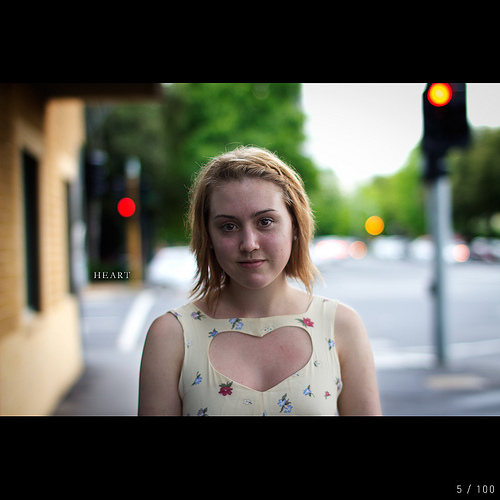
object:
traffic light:
[117, 197, 137, 219]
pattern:
[206, 323, 313, 395]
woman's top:
[162, 292, 347, 417]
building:
[0, 74, 83, 416]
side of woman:
[134, 307, 189, 415]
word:
[94, 271, 102, 280]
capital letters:
[93, 271, 131, 280]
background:
[77, 82, 499, 414]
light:
[427, 82, 454, 108]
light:
[364, 215, 385, 237]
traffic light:
[423, 81, 458, 108]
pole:
[427, 175, 452, 373]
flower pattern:
[277, 393, 294, 415]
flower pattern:
[191, 370, 203, 387]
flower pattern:
[228, 318, 244, 331]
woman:
[134, 142, 381, 417]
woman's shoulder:
[140, 305, 198, 357]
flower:
[217, 380, 233, 397]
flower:
[293, 316, 315, 329]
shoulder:
[301, 296, 371, 353]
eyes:
[219, 223, 239, 233]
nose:
[239, 226, 260, 253]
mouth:
[233, 258, 268, 270]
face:
[209, 177, 295, 290]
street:
[54, 234, 497, 417]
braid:
[221, 159, 289, 186]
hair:
[184, 143, 327, 306]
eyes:
[256, 218, 274, 228]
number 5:
[456, 484, 464, 494]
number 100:
[476, 482, 497, 495]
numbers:
[456, 484, 463, 494]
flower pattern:
[302, 384, 315, 399]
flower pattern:
[325, 337, 335, 351]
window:
[18, 156, 43, 318]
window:
[65, 177, 75, 297]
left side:
[2, 78, 37, 418]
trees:
[114, 78, 168, 154]